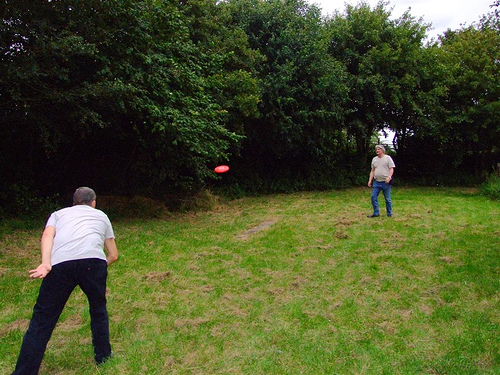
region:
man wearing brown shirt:
[377, 163, 389, 178]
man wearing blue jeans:
[371, 185, 378, 197]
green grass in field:
[346, 253, 409, 323]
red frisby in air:
[207, 157, 234, 177]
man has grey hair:
[376, 142, 384, 149]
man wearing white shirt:
[66, 227, 83, 247]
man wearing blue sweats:
[49, 284, 60, 310]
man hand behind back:
[24, 259, 51, 286]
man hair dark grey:
[75, 188, 91, 205]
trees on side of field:
[172, 84, 207, 122]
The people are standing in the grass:
[20, 28, 496, 373]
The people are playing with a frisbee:
[15, 31, 483, 371]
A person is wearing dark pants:
[13, 56, 448, 372]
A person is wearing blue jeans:
[325, 103, 420, 244]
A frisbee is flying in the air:
[168, 136, 275, 226]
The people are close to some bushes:
[20, 30, 488, 372]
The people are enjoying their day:
[15, 26, 450, 373]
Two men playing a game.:
[7, 140, 394, 370]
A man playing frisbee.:
[15, 162, 234, 369]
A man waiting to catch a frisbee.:
[361, 140, 399, 217]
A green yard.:
[12, 180, 494, 373]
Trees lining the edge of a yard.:
[1, 4, 492, 204]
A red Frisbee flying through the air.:
[211, 162, 229, 175]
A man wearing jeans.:
[361, 141, 397, 221]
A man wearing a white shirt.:
[10, 184, 123, 369]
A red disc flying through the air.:
[209, 161, 232, 176]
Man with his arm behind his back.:
[12, 185, 122, 370]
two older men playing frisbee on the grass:
[20, 54, 435, 343]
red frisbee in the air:
[201, 157, 242, 180]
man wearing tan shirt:
[360, 135, 402, 214]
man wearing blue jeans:
[357, 133, 404, 223]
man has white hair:
[362, 127, 408, 218]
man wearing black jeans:
[24, 175, 128, 359]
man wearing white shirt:
[22, 175, 133, 367]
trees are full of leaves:
[12, 5, 473, 174]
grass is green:
[37, 177, 477, 355]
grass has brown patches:
[29, 195, 481, 359]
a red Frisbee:
[207, 160, 229, 172]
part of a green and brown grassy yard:
[205, 179, 498, 374]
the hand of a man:
[23, 260, 51, 281]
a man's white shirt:
[47, 206, 118, 268]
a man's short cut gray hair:
[71, 186, 97, 204]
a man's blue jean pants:
[363, 180, 393, 217]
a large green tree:
[330, 3, 429, 133]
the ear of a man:
[90, 195, 97, 207]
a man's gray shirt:
[369, 152, 396, 182]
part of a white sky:
[421, 5, 474, 24]